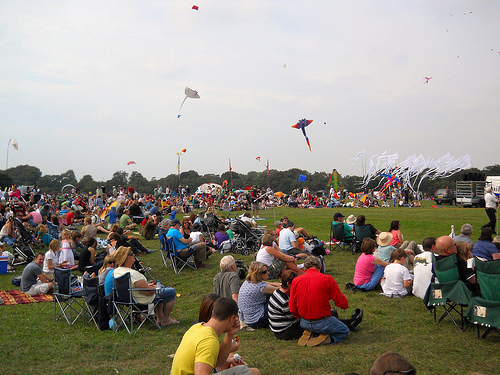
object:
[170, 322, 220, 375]
shirt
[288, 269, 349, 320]
shirt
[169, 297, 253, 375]
person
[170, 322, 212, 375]
back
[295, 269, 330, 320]
person's back